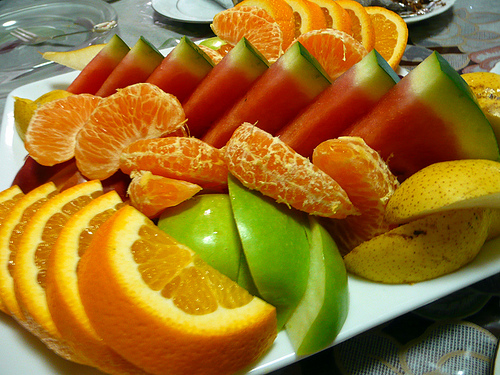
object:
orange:
[0, 181, 276, 375]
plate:
[0, 34, 500, 375]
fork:
[11, 21, 115, 47]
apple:
[223, 171, 311, 307]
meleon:
[342, 49, 494, 155]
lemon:
[313, 138, 397, 256]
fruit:
[0, 0, 494, 375]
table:
[455, 44, 479, 63]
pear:
[384, 160, 500, 224]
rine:
[239, 213, 296, 283]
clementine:
[119, 136, 228, 213]